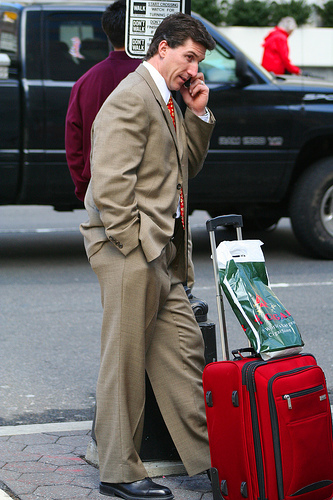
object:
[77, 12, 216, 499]
man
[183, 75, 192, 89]
cellphone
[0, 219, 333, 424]
street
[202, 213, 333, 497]
luggage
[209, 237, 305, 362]
shopping bag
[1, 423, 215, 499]
sidewalk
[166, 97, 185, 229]
tie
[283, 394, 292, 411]
zipper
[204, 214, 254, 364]
handle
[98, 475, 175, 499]
right shoe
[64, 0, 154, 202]
man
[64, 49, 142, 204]
shirt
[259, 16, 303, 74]
woman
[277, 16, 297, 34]
hair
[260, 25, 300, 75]
jacket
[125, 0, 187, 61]
crossing sign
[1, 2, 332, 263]
truck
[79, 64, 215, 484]
suit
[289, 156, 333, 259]
tire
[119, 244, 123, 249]
buttons